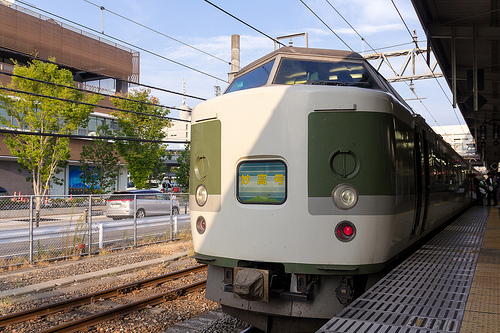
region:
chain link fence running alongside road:
[3, 190, 190, 267]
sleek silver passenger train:
[186, 43, 488, 321]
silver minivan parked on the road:
[104, 185, 181, 220]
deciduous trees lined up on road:
[6, 47, 193, 227]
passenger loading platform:
[318, 198, 498, 324]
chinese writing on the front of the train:
[238, 171, 285, 187]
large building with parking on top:
[4, 3, 133, 199]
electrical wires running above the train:
[206, 2, 494, 155]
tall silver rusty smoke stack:
[228, 30, 241, 82]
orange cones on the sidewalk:
[10, 188, 76, 205]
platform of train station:
[324, 201, 497, 331]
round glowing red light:
[335, 221, 354, 241]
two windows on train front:
[224, 56, 382, 95]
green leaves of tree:
[7, 58, 96, 185]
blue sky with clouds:
[20, 0, 462, 125]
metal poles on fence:
[0, 192, 189, 267]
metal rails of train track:
[0, 269, 201, 331]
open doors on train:
[409, 124, 431, 236]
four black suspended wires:
[0, 46, 200, 148]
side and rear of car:
[105, 186, 178, 220]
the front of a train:
[185, 41, 401, 320]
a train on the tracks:
[198, 40, 497, 317]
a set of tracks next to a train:
[7, 262, 204, 330]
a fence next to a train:
[3, 185, 194, 255]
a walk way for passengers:
[316, 201, 477, 321]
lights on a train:
[187, 181, 362, 248]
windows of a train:
[216, 55, 384, 92]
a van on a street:
[103, 188, 179, 219]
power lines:
[1, 47, 191, 155]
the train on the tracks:
[179, 41, 405, 294]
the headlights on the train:
[189, 180, 366, 219]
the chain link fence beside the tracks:
[3, 190, 182, 272]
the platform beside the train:
[343, 219, 492, 329]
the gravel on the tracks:
[121, 318, 171, 332]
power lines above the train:
[271, 4, 418, 65]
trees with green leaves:
[21, 68, 170, 171]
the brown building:
[6, 13, 126, 200]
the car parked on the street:
[107, 184, 184, 234]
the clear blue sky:
[246, 10, 294, 36]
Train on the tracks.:
[169, 22, 473, 331]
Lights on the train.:
[141, 110, 391, 254]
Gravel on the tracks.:
[81, 243, 203, 331]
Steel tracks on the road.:
[129, 239, 227, 331]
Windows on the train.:
[226, 50, 449, 122]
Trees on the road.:
[10, 57, 192, 280]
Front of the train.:
[195, 252, 355, 324]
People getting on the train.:
[437, 137, 499, 213]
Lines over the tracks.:
[121, 20, 246, 150]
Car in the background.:
[92, 177, 187, 237]